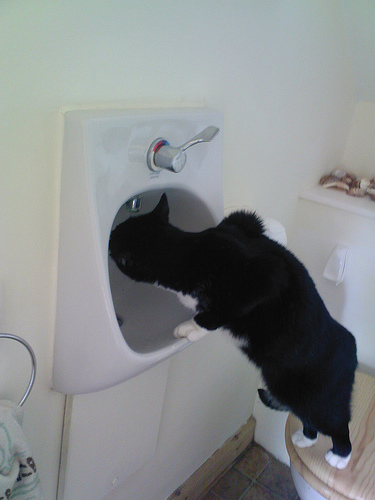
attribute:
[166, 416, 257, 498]
baseboard — unpainted, wooden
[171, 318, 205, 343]
foot — white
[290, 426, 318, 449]
foot — white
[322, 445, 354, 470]
foot — white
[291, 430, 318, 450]
foot — white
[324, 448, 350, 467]
foot — white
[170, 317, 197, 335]
foot — white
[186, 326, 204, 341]
foot — white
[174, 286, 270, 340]
leg — black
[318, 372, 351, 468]
leg — black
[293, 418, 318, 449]
leg — black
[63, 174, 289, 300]
cat — black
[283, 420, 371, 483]
feet — white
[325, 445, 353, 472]
paw — white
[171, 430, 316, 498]
floor — tiled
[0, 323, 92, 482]
hoop — metal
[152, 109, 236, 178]
knob — silver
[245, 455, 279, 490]
floor — tile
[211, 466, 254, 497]
tile — flooring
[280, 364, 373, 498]
toilet seat — wooden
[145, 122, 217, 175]
handle — metal, harware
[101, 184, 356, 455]
cat — drinking, standing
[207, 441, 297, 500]
tiles — colored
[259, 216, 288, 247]
toilet paper — white, edge